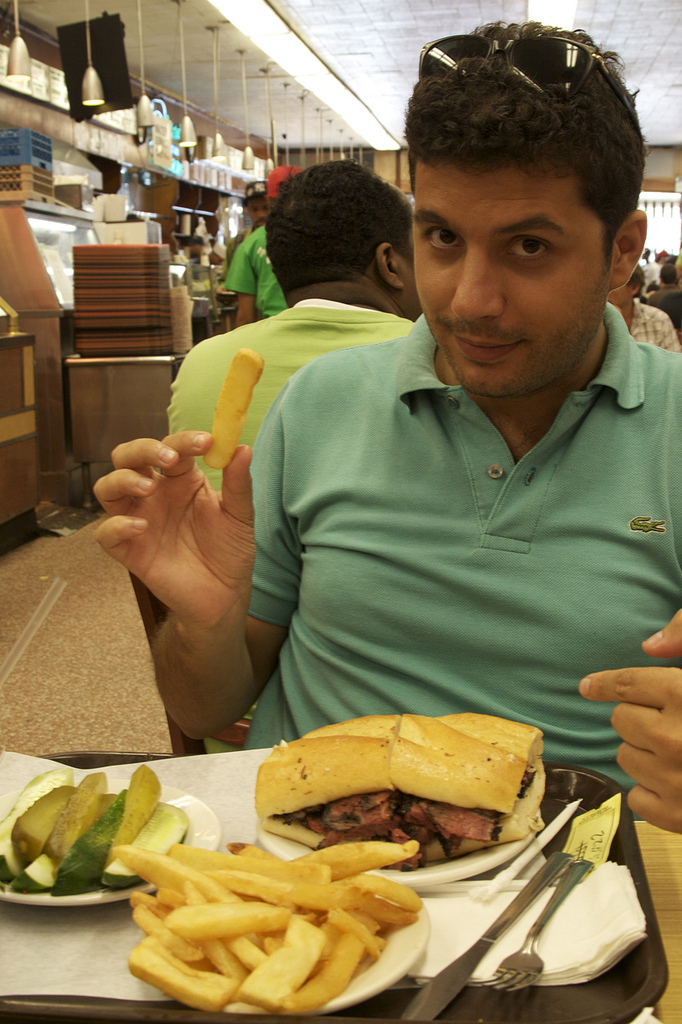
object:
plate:
[0, 779, 222, 907]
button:
[488, 463, 503, 478]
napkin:
[407, 860, 647, 984]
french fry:
[198, 353, 269, 473]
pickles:
[0, 764, 187, 896]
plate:
[258, 827, 535, 890]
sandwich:
[255, 711, 545, 871]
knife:
[401, 851, 572, 1021]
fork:
[482, 860, 594, 992]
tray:
[0, 751, 668, 1023]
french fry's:
[111, 840, 422, 1013]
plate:
[318, 904, 429, 1013]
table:
[633, 819, 680, 1022]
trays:
[72, 244, 174, 358]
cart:
[65, 356, 186, 464]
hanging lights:
[137, 0, 155, 125]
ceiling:
[210, 0, 400, 151]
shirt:
[247, 303, 681, 790]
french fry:
[203, 348, 265, 469]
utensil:
[397, 851, 595, 1022]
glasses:
[419, 35, 609, 100]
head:
[403, 19, 647, 399]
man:
[93, 21, 682, 840]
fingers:
[579, 604, 680, 833]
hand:
[93, 430, 256, 629]